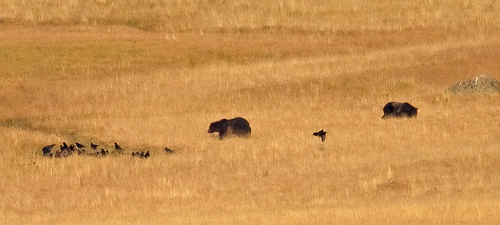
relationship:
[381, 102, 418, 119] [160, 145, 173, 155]
bear close to bird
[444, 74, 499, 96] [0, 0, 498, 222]
rock in field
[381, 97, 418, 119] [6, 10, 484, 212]
bear in pasture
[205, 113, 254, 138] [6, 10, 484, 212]
bear in pasture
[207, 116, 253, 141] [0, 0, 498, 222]
bear in field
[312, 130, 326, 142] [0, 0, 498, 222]
bird in field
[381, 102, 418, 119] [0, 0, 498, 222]
bear in field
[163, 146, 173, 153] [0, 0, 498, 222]
bird in field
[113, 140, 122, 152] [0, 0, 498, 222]
bird in field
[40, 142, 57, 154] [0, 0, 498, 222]
bird in field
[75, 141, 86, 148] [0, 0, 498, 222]
bird in field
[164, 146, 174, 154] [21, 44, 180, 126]
birds gathered in field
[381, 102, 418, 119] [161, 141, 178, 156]
bear walking away from bird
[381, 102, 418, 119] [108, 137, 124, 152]
bear walking away from bird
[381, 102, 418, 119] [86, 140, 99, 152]
bear walking away from bird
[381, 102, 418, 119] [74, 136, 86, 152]
bear walking away from bird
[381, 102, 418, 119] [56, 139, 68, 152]
bear walking away from bird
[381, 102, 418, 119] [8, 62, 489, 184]
bear in field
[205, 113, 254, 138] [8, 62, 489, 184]
bear in field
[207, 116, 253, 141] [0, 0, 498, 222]
bear on field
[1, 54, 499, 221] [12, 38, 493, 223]
field of grass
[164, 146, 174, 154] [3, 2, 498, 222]
birds eating off ground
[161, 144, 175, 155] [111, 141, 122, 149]
birds on birds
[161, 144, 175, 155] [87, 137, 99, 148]
birds on birds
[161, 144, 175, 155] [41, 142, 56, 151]
birds on birds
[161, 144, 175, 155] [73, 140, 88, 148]
birds on birds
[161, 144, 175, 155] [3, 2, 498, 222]
birds on ground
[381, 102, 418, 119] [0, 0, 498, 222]
bear on field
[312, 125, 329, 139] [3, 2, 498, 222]
bird near ground